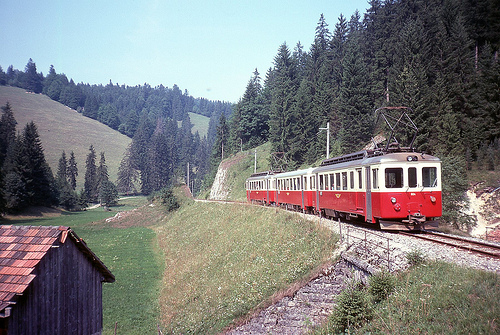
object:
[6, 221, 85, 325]
shingles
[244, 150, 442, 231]
car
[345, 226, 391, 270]
fence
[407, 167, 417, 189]
window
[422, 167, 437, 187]
window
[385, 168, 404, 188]
window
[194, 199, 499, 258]
track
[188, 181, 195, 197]
bridge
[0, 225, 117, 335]
barn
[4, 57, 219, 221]
hillside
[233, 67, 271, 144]
trees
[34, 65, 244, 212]
pine trees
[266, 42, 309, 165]
trees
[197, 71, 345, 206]
hills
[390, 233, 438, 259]
gravel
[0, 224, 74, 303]
roof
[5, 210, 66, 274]
shingles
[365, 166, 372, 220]
doors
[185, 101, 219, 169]
smoke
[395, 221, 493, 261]
rail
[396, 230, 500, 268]
rocks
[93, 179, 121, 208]
tree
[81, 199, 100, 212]
road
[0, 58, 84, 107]
trees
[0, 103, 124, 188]
hill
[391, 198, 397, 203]
lights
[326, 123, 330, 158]
pole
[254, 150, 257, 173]
pole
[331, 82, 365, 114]
leaves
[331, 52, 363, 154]
tree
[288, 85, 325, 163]
tree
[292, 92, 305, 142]
leaves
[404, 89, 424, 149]
leaves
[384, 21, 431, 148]
tree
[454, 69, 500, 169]
tree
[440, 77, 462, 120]
leaves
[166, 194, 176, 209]
leaves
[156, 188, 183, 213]
tree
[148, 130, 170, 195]
tree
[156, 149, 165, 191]
leaves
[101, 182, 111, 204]
leaves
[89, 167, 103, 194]
leaves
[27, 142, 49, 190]
leaves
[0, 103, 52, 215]
tree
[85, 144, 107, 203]
tree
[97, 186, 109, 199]
leaves